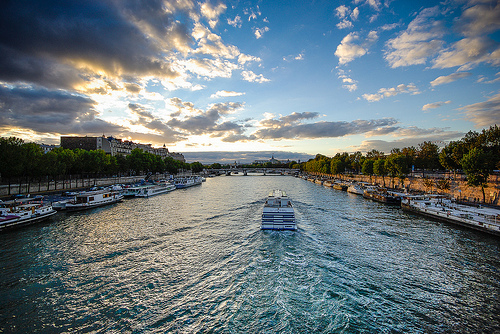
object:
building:
[254, 156, 304, 176]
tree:
[372, 148, 402, 185]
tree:
[73, 148, 119, 187]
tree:
[330, 157, 344, 178]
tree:
[125, 147, 155, 181]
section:
[467, 161, 479, 174]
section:
[377, 167, 384, 174]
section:
[335, 163, 340, 170]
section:
[92, 158, 102, 169]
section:
[136, 156, 143, 165]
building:
[252, 154, 297, 166]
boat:
[173, 171, 205, 188]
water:
[1, 170, 496, 331]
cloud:
[2, 1, 217, 99]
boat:
[259, 185, 297, 230]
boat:
[52, 185, 123, 211]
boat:
[173, 167, 203, 188]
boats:
[354, 182, 497, 229]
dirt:
[455, 182, 495, 204]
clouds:
[178, 12, 431, 86]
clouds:
[334, 10, 473, 92]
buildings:
[58, 135, 187, 163]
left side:
[0, 0, 253, 332]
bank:
[339, 189, 442, 206]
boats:
[2, 163, 202, 230]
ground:
[387, 175, 496, 190]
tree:
[459, 143, 499, 204]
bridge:
[208, 159, 298, 172]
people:
[262, 193, 292, 207]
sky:
[5, 37, 455, 107]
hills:
[36, 141, 62, 152]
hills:
[246, 157, 296, 164]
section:
[266, 185, 289, 196]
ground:
[402, 100, 429, 127]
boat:
[1, 196, 60, 231]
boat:
[304, 170, 314, 184]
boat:
[312, 171, 323, 186]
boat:
[320, 177, 337, 189]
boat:
[347, 177, 370, 196]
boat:
[365, 177, 433, 211]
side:
[299, 177, 497, 231]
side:
[1, 157, 206, 268]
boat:
[123, 178, 176, 198]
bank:
[0, 175, 80, 203]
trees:
[291, 132, 499, 184]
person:
[263, 202, 269, 205]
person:
[286, 200, 291, 205]